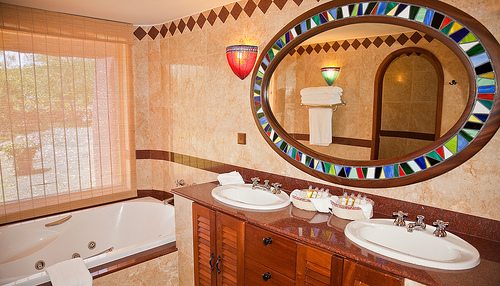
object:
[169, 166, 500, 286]
paneled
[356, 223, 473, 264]
sink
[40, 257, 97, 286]
towel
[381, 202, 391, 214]
ground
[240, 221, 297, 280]
drawer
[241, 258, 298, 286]
drawer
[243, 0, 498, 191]
mirror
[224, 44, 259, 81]
sconce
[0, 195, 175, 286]
bathtub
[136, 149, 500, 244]
border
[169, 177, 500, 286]
table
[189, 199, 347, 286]
cabinets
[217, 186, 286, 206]
sink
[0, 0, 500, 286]
picture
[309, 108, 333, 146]
towels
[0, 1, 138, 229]
window shade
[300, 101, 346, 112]
holders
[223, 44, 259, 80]
light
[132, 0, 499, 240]
wall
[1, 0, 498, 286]
bathroom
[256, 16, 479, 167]
reflection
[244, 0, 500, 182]
pattern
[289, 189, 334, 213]
basket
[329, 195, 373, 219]
basket